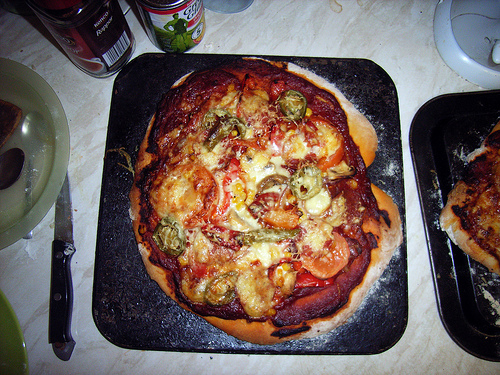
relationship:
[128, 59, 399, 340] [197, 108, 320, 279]
pizza has middle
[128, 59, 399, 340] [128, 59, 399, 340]
pizza has pizza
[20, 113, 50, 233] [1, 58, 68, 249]
spoon underneath plate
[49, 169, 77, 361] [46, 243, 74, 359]
knife has handle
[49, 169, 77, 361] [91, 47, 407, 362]
knife beside pan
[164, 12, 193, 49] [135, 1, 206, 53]
giant on can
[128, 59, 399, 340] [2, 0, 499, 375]
pizza on table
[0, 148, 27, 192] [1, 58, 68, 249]
spoon on plate